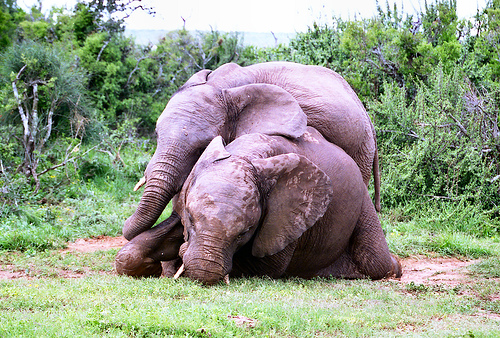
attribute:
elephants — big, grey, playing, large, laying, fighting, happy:
[140, 68, 417, 290]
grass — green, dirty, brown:
[63, 270, 493, 336]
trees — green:
[359, 19, 498, 158]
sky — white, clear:
[194, 1, 316, 37]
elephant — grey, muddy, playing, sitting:
[188, 150, 332, 270]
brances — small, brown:
[40, 146, 117, 176]